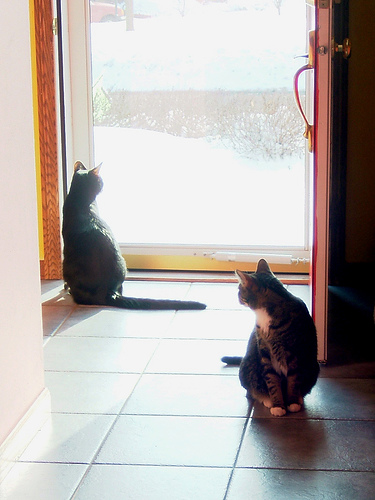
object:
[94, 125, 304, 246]
snow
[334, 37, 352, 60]
handle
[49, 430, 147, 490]
light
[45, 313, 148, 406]
light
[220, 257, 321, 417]
cat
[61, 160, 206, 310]
cat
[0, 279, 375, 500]
floor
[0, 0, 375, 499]
house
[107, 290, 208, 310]
tail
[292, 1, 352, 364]
door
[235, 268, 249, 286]
ear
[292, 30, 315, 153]
handle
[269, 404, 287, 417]
paw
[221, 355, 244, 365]
tail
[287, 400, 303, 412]
paw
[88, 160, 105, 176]
ear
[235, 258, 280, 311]
head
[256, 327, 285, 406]
fore leg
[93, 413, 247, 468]
tile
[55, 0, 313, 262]
window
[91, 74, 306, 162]
plants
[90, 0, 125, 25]
car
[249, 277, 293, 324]
neck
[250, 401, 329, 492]
shadow